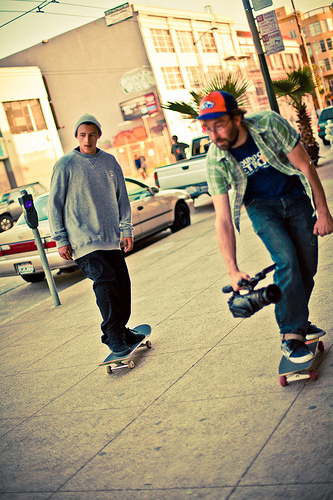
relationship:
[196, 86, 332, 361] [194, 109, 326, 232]
man wearing squared shirt.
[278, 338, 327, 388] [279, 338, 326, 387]
wheels are on skateboard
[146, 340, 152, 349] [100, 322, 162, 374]
wheel on skateboard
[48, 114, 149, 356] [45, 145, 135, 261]
man wearing a grey top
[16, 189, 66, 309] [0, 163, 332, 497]
parking meter on sidewalk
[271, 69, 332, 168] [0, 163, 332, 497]
palm tree on sidewalk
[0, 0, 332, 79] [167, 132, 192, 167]
power lines above a person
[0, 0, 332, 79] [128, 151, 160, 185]
power lines above a person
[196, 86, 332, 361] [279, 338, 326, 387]
guy on skateboard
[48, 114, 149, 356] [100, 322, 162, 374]
guy on top of a skateboard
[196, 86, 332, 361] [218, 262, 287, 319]
man with a camera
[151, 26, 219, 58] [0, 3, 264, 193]
windows of a building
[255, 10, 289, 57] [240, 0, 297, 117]
sign on a pole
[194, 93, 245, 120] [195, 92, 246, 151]
hat on top of head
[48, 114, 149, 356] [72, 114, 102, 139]
man wearing a beanie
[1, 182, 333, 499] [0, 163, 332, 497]
title shaped blocks in sidewalk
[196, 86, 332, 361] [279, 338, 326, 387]
man standing on top of skateboard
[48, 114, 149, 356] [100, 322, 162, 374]
man standing on top of skateboard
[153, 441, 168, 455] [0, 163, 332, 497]
stain on top of pavement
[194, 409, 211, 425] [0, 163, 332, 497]
stain on top of pavement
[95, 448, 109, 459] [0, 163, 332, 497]
stain on top of pavement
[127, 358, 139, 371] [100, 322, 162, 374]
wheel on bottom of skateboard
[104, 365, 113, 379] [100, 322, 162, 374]
wheel on bottom of skateboard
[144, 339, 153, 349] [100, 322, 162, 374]
wheel on bottom of skateboard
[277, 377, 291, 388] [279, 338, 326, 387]
wheel on bottom of skateboard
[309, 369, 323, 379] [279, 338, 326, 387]
wheel on bottom of skateboard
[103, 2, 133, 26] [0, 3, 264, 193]
sign on building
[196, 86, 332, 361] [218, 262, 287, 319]
man holding video camera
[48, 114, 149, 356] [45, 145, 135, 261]
man wearing a sweatshirt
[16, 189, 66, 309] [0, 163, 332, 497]
parking meter next to sidewalk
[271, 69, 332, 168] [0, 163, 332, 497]
palm tree next to sidewalk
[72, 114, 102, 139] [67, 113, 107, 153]
cap on top of guy's head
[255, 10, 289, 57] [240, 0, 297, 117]
signs on a pole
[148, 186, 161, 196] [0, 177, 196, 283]
mirror on car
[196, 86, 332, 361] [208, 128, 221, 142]
man has a nose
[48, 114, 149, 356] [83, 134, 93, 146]
man has a nose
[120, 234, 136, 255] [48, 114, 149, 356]
hand of man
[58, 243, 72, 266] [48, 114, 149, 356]
hand of man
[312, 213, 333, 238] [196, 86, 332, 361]
hand of man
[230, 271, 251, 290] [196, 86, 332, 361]
hand of man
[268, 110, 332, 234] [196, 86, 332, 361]
arm of man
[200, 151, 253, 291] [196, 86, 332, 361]
arm of man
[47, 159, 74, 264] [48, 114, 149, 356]
arm of man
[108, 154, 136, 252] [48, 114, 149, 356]
arm of man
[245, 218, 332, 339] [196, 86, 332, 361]
legs of man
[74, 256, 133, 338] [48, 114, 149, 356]
legs of man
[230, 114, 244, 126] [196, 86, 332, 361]
ear of man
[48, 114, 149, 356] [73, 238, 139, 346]
man wearing pants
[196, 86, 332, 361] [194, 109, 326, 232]
man wearing a shirt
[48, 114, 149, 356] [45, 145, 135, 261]
man wearing a shirt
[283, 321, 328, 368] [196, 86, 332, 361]
feet of man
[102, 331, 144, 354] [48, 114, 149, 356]
feet of man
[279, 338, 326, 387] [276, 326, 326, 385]
red wheels on skateboard